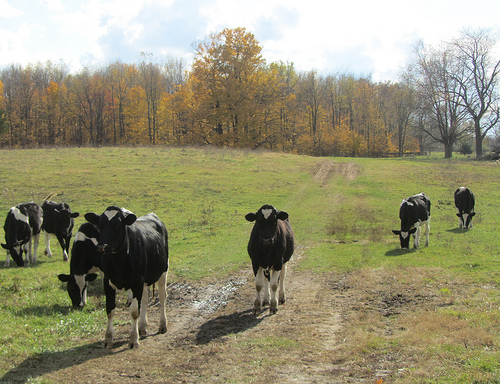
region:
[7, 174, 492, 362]
a herd of cattle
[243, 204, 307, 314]
a black and white cow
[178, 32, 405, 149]
yeloow trees in the distance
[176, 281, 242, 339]
a muddy puddle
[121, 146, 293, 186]
green grass on pasture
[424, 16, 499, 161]
bare trees with no leaves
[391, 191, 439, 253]
a cow eating grass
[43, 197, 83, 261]
a cow walking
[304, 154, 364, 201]
a dirt road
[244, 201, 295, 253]
a cows black and white head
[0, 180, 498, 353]
Group of black and white colored cows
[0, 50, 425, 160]
Trees with yellowing leaves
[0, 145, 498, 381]
Grazing field with sparce grass cover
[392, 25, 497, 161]
Trees with leaves fallen off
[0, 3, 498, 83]
Cloud filled blue sky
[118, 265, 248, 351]
Slight mud pool on a track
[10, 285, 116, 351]
Pool of water in the grass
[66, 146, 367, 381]
Passage with vehicle tracks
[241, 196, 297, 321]
Cow standing straight up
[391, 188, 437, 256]
Cow grazing in the field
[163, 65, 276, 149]
Yellow leaves on a tree.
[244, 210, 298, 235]
Two cow ears facing camera.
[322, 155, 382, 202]
Patch of dirt tracks in the grass.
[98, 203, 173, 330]
Big cow facing camera.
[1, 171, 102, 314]
Three cows eating grass.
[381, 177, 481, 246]
Two cows on the left eating grass.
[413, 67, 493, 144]
Trees without leaves on the left.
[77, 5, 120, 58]
Small white clouds in the sky.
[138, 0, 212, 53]
Small clear sky next to clouds.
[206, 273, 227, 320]
Small puddle of dirt.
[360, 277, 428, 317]
dirt on the ground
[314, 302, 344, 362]
white spot on the ground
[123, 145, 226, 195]
green grass in the field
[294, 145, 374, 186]
tracks on the grass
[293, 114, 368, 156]
yellow trees in the back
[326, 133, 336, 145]
yellow leaves on the trees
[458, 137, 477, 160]
small green tree in the distance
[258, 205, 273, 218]
white spot in cow's face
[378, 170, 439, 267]
cow grazing on grass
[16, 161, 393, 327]
cows in the field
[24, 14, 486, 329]
picture taken outdoors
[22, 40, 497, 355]
picture taken outside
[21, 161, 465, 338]
cows on a pasture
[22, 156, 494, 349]
the cows are black and white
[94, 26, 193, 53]
the sky is full of clouds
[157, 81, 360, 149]
the trees leaves are yellow and brown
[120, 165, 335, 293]
the cows are walking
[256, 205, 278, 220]
the cow has a white triangle on head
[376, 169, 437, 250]
the cow is feeding